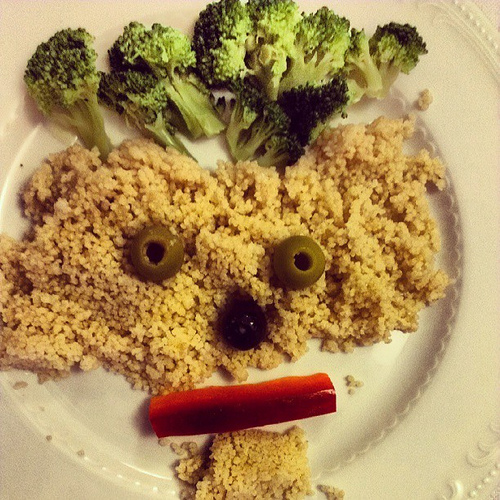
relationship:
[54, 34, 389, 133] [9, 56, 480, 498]
broccoli on plate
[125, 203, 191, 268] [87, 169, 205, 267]
olive on left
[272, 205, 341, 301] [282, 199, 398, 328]
olive on right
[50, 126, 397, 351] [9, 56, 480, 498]
rice on plate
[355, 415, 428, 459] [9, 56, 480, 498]
design on plate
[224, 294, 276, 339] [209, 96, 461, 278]
olive in center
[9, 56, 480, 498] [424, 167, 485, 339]
plate has ridges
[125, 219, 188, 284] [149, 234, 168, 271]
olive have holes